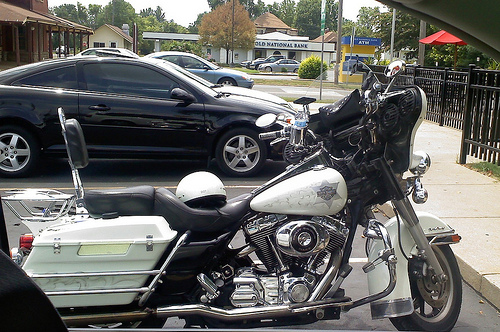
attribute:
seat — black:
[57, 113, 254, 228]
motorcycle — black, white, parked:
[10, 62, 471, 325]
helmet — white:
[170, 168, 230, 213]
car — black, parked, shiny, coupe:
[2, 48, 291, 176]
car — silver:
[139, 50, 258, 87]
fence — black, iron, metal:
[366, 59, 499, 168]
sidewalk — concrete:
[409, 84, 499, 300]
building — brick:
[0, 1, 55, 66]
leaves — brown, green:
[197, 3, 258, 50]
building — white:
[145, 20, 335, 77]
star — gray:
[313, 177, 344, 209]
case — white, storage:
[14, 215, 174, 292]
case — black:
[318, 88, 365, 133]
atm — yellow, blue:
[337, 35, 382, 87]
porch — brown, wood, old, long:
[2, 23, 92, 71]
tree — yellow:
[203, 1, 255, 65]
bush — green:
[297, 55, 329, 81]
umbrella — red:
[417, 26, 466, 49]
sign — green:
[316, 1, 331, 40]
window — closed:
[81, 58, 181, 99]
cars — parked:
[2, 43, 294, 173]